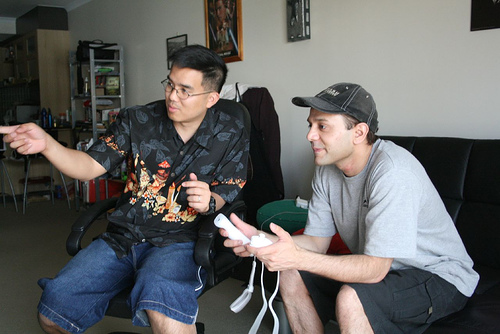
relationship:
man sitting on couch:
[228, 79, 482, 331] [315, 137, 496, 332]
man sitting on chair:
[105, 52, 252, 282] [35, 169, 300, 331]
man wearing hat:
[228, 79, 482, 331] [291, 75, 383, 130]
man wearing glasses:
[0, 44, 249, 333] [155, 73, 213, 100]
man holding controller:
[228, 79, 482, 331] [213, 212, 246, 244]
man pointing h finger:
[0, 44, 249, 333] [2, 119, 37, 134]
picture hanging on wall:
[204, 0, 243, 63] [36, 0, 498, 211]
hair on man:
[167, 42, 228, 94] [3, 49, 276, 332]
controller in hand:
[212, 212, 271, 249] [216, 209, 303, 272]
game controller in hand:
[248, 232, 272, 252] [244, 221, 296, 273]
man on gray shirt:
[228, 79, 482, 331] [303, 138, 480, 298]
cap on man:
[291, 80, 383, 131] [228, 79, 482, 331]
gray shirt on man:
[303, 138, 480, 298] [228, 79, 482, 331]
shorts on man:
[296, 254, 468, 334] [228, 79, 482, 331]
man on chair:
[0, 44, 249, 333] [66, 86, 284, 334]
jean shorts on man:
[37, 233, 206, 333] [57, 65, 210, 325]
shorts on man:
[290, 251, 468, 331] [228, 79, 482, 331]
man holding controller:
[218, 82, 480, 334] [213, 212, 254, 257]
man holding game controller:
[218, 82, 480, 334] [250, 232, 272, 248]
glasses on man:
[160, 74, 216, 97] [3, 49, 276, 332]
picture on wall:
[288, 1, 312, 39] [68, 1, 496, 199]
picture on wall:
[202, 0, 246, 60] [68, 1, 496, 199]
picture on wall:
[165, 31, 188, 71] [68, 1, 496, 199]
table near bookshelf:
[1, 101, 91, 212] [11, 29, 79, 191]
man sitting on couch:
[228, 79, 482, 331] [373, 127, 493, 321]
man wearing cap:
[228, 79, 482, 331] [291, 82, 380, 132]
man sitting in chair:
[0, 44, 249, 333] [62, 98, 255, 331]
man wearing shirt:
[0, 44, 249, 333] [83, 95, 254, 257]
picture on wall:
[469, 0, 498, 34] [68, 1, 496, 199]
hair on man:
[172, 45, 229, 95] [0, 44, 249, 333]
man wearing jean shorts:
[0, 44, 249, 333] [39, 234, 201, 330]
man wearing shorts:
[228, 79, 482, 331] [297, 268, 470, 331]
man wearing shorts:
[0, 44, 249, 333] [32, 241, 205, 331]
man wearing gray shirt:
[228, 79, 482, 331] [294, 133, 483, 301]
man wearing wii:
[228, 79, 482, 331] [208, 206, 279, 332]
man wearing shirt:
[228, 79, 482, 331] [282, 140, 489, 317]